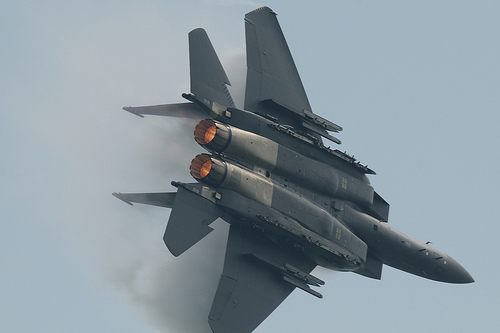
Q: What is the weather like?
A: It is clear.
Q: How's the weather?
A: It is clear.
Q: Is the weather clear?
A: Yes, it is clear.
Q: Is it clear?
A: Yes, it is clear.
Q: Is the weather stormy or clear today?
A: It is clear.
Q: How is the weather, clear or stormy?
A: It is clear.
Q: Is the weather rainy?
A: No, it is clear.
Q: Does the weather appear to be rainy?
A: No, it is clear.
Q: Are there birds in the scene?
A: No, there are no birds.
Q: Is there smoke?
A: Yes, there is smoke.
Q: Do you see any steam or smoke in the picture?
A: Yes, there is smoke.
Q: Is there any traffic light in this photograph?
A: No, there are no traffic lights.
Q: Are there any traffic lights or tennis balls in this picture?
A: No, there are no traffic lights or tennis balls.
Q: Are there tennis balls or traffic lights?
A: No, there are no traffic lights or tennis balls.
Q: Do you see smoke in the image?
A: Yes, there is smoke.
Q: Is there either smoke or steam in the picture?
A: Yes, there is smoke.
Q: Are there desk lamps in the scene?
A: No, there are no desk lamps.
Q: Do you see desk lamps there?
A: No, there are no desk lamps.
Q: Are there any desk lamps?
A: No, there are no desk lamps.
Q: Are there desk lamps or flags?
A: No, there are no desk lamps or flags.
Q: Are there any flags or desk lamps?
A: No, there are no desk lamps or flags.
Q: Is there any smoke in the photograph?
A: Yes, there is smoke.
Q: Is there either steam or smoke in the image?
A: Yes, there is smoke.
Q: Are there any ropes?
A: No, there are no ropes.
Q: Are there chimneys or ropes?
A: No, there are no ropes or chimneys.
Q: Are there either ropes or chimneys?
A: No, there are no ropes or chimneys.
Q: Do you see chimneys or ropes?
A: No, there are no ropes or chimneys.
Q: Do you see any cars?
A: No, there are no cars.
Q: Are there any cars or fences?
A: No, there are no cars or fences.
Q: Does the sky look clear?
A: Yes, the sky is clear.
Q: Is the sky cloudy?
A: No, the sky is clear.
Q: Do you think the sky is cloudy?
A: No, the sky is clear.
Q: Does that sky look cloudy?
A: No, the sky is clear.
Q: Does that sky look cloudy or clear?
A: The sky is clear.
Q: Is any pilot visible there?
A: No, there are no pilots.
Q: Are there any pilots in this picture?
A: No, there are no pilots.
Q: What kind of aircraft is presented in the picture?
A: The aircraft is a jet.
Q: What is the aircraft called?
A: The aircraft is a jet.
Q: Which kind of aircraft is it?
A: The aircraft is a jet.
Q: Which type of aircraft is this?
A: That is a jet.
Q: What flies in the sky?
A: The jet flies in the sky.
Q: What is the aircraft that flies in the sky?
A: The aircraft is a jet.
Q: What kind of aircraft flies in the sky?
A: The aircraft is a jet.